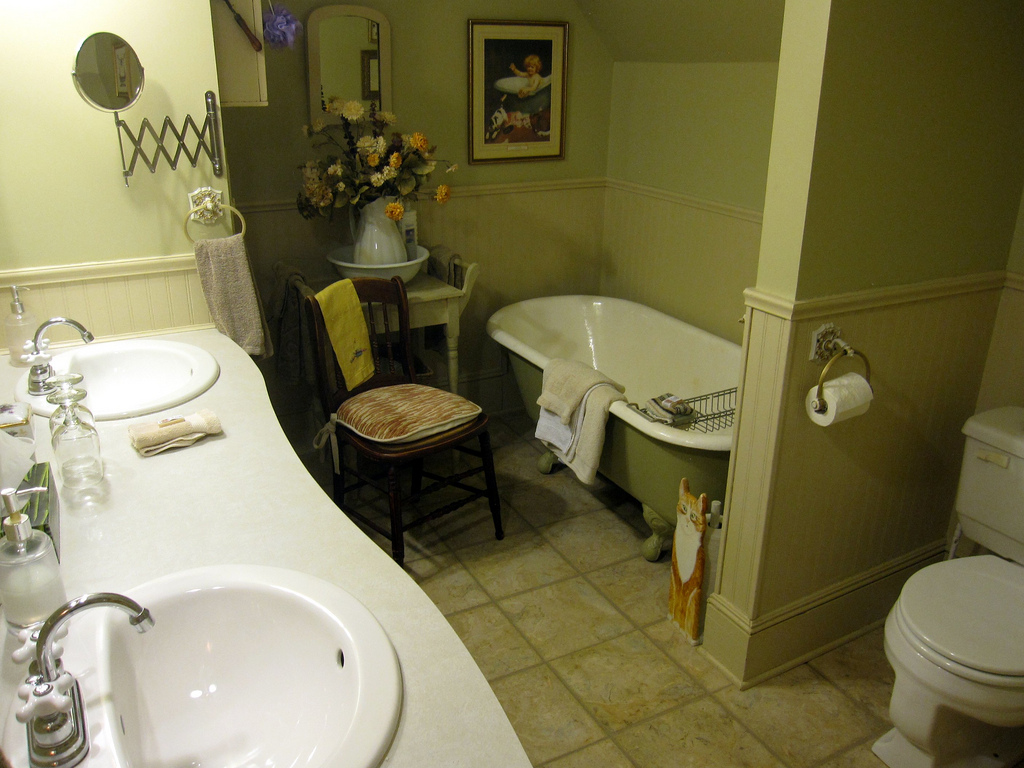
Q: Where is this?
A: This is at the bathroom.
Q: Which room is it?
A: It is a bathroom.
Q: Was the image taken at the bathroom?
A: Yes, it was taken in the bathroom.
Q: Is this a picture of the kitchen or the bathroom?
A: It is showing the bathroom.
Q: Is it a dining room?
A: No, it is a bathroom.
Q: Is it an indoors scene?
A: Yes, it is indoors.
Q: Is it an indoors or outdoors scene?
A: It is indoors.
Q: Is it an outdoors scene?
A: No, it is indoors.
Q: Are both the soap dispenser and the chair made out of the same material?
A: No, the soap dispenser is made of glass and the chair is made of wood.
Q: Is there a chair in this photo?
A: Yes, there is a chair.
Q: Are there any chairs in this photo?
A: Yes, there is a chair.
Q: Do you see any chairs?
A: Yes, there is a chair.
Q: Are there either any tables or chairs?
A: Yes, there is a chair.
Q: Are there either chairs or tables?
A: Yes, there is a chair.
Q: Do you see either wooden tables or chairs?
A: Yes, there is a wood chair.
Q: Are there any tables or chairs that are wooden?
A: Yes, the chair is wooden.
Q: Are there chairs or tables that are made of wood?
A: Yes, the chair is made of wood.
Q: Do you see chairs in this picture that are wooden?
A: Yes, there is a wood chair.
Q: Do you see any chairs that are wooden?
A: Yes, there is a chair that is wooden.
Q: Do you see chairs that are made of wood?
A: Yes, there is a chair that is made of wood.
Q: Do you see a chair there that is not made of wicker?
A: Yes, there is a chair that is made of wood.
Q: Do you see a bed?
A: No, there are no beds.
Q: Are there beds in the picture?
A: No, there are no beds.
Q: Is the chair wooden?
A: Yes, the chair is wooden.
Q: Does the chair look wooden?
A: Yes, the chair is wooden.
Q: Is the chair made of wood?
A: Yes, the chair is made of wood.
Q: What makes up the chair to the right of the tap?
A: The chair is made of wood.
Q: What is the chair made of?
A: The chair is made of wood.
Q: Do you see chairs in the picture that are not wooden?
A: No, there is a chair but it is wooden.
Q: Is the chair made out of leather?
A: No, the chair is made of wood.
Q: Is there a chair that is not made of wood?
A: No, there is a chair but it is made of wood.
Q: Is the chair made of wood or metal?
A: The chair is made of wood.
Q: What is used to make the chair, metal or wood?
A: The chair is made of wood.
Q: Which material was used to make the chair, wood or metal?
A: The chair is made of wood.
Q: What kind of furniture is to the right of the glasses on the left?
A: The piece of furniture is a chair.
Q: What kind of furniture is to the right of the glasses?
A: The piece of furniture is a chair.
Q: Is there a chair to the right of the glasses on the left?
A: Yes, there is a chair to the right of the glasses.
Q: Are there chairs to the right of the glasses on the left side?
A: Yes, there is a chair to the right of the glasses.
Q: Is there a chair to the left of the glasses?
A: No, the chair is to the right of the glasses.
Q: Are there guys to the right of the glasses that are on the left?
A: No, there is a chair to the right of the glasses.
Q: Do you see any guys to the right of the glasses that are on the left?
A: No, there is a chair to the right of the glasses.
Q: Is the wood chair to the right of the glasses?
A: Yes, the chair is to the right of the glasses.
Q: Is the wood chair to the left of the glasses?
A: No, the chair is to the right of the glasses.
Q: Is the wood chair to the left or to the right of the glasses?
A: The chair is to the right of the glasses.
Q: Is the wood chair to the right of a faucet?
A: Yes, the chair is to the right of a faucet.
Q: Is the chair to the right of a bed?
A: No, the chair is to the right of a faucet.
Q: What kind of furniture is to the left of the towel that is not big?
A: The piece of furniture is a chair.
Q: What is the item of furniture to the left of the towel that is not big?
A: The piece of furniture is a chair.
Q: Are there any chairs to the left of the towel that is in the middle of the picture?
A: Yes, there is a chair to the left of the towel.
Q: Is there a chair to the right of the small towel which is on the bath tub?
A: No, the chair is to the left of the towel.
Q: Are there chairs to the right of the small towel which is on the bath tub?
A: No, the chair is to the left of the towel.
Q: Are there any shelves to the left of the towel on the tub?
A: No, there is a chair to the left of the towel.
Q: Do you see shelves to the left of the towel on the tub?
A: No, there is a chair to the left of the towel.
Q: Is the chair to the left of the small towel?
A: Yes, the chair is to the left of the towel.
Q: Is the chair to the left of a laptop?
A: No, the chair is to the left of the towel.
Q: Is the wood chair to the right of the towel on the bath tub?
A: No, the chair is to the left of the towel.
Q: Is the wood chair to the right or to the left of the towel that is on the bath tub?
A: The chair is to the left of the towel.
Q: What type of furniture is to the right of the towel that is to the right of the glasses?
A: The piece of furniture is a chair.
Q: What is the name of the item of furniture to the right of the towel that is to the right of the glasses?
A: The piece of furniture is a chair.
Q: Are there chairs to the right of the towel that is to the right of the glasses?
A: Yes, there is a chair to the right of the towel.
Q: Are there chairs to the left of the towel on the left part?
A: No, the chair is to the right of the towel.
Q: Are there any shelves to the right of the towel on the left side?
A: No, there is a chair to the right of the towel.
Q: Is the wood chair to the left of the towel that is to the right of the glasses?
A: No, the chair is to the right of the towel.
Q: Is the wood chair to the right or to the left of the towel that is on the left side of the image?
A: The chair is to the right of the towel.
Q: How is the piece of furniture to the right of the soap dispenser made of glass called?
A: The piece of furniture is a chair.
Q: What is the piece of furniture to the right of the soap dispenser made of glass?
A: The piece of furniture is a chair.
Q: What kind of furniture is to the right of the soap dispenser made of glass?
A: The piece of furniture is a chair.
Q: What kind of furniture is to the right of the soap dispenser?
A: The piece of furniture is a chair.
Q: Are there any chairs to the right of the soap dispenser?
A: Yes, there is a chair to the right of the soap dispenser.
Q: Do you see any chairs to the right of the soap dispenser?
A: Yes, there is a chair to the right of the soap dispenser.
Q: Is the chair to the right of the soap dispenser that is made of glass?
A: Yes, the chair is to the right of the soap dispenser.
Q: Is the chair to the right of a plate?
A: No, the chair is to the right of the soap dispenser.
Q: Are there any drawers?
A: No, there are no drawers.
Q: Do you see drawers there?
A: No, there are no drawers.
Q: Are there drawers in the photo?
A: No, there are no drawers.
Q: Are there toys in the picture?
A: No, there are no toys.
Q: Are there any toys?
A: No, there are no toys.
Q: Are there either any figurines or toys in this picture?
A: No, there are no toys or figurines.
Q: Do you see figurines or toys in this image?
A: No, there are no toys or figurines.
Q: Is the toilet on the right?
A: Yes, the toilet is on the right of the image.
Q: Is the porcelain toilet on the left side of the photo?
A: No, the toilet is on the right of the image.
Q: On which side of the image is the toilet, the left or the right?
A: The toilet is on the right of the image.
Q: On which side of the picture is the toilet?
A: The toilet is on the right of the image.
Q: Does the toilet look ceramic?
A: Yes, the toilet is ceramic.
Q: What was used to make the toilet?
A: The toilet is made of porcelain.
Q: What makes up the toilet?
A: The toilet is made of porcelain.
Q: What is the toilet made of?
A: The toilet is made of porcelain.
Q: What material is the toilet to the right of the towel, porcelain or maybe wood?
A: The toilet is made of porcelain.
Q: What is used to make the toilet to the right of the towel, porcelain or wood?
A: The toilet is made of porcelain.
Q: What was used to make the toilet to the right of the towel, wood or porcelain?
A: The toilet is made of porcelain.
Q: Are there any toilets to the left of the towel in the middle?
A: No, the toilet is to the right of the towel.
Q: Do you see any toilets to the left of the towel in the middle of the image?
A: No, the toilet is to the right of the towel.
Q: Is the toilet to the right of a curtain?
A: No, the toilet is to the right of a towel.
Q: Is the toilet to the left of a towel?
A: No, the toilet is to the right of a towel.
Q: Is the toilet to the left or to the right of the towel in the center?
A: The toilet is to the right of the towel.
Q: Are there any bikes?
A: No, there are no bikes.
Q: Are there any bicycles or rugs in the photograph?
A: No, there are no bicycles or rugs.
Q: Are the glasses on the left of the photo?
A: Yes, the glasses are on the left of the image.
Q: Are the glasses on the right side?
A: No, the glasses are on the left of the image.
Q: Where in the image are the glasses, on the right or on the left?
A: The glasses are on the left of the image.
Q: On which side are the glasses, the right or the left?
A: The glasses are on the left of the image.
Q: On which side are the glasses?
A: The glasses are on the left of the image.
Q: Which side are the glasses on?
A: The glasses are on the left of the image.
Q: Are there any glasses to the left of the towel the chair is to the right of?
A: Yes, there are glasses to the left of the towel.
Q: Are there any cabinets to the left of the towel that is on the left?
A: No, there are glasses to the left of the towel.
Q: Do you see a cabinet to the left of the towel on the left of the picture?
A: No, there are glasses to the left of the towel.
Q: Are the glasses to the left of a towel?
A: Yes, the glasses are to the left of a towel.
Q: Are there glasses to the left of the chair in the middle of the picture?
A: Yes, there are glasses to the left of the chair.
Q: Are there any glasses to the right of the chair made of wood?
A: No, the glasses are to the left of the chair.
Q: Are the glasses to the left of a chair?
A: Yes, the glasses are to the left of a chair.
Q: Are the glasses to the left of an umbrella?
A: No, the glasses are to the left of a chair.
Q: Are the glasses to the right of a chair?
A: No, the glasses are to the left of a chair.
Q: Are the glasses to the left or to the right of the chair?
A: The glasses are to the left of the chair.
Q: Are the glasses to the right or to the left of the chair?
A: The glasses are to the left of the chair.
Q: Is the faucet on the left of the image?
A: Yes, the faucet is on the left of the image.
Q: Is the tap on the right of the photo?
A: No, the tap is on the left of the image.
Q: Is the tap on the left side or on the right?
A: The tap is on the left of the image.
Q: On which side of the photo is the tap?
A: The tap is on the left of the image.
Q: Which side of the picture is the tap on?
A: The tap is on the left of the image.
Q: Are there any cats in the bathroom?
A: No, there is a faucet in the bathroom.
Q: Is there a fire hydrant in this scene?
A: No, there are no fire hydrants.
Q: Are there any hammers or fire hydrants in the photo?
A: No, there are no fire hydrants or hammers.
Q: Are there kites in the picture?
A: No, there are no kites.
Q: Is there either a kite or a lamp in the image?
A: No, there are no kites or lamps.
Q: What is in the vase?
A: The flowers are in the vase.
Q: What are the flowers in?
A: The flowers are in the vase.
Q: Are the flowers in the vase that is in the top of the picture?
A: Yes, the flowers are in the vase.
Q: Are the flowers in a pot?
A: No, the flowers are in the vase.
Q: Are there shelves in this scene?
A: No, there are no shelves.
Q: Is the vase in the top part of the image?
A: Yes, the vase is in the top of the image.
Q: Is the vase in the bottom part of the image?
A: No, the vase is in the top of the image.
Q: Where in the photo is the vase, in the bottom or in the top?
A: The vase is in the top of the image.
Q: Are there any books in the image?
A: No, there are no books.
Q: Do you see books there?
A: No, there are no books.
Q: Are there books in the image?
A: No, there are no books.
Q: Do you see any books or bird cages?
A: No, there are no books or bird cages.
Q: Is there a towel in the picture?
A: Yes, there is a towel.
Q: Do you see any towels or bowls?
A: Yes, there is a towel.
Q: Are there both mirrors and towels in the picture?
A: Yes, there are both a towel and a mirror.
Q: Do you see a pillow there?
A: No, there are no pillows.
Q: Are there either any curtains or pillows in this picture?
A: No, there are no pillows or curtains.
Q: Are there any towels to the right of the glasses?
A: Yes, there is a towel to the right of the glasses.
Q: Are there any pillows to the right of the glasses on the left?
A: No, there is a towel to the right of the glasses.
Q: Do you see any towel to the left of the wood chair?
A: Yes, there is a towel to the left of the chair.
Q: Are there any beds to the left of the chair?
A: No, there is a towel to the left of the chair.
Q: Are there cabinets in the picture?
A: No, there are no cabinets.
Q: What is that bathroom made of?
A: The bathroom is made of porcelain.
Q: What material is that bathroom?
A: The bathroom is made of porcelain.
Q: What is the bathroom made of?
A: The bathroom is made of porcelain.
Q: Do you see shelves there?
A: No, there are no shelves.